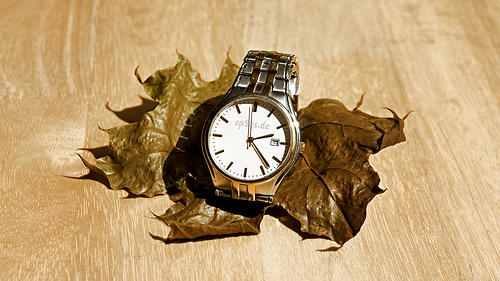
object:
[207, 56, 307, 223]
watch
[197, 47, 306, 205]
watch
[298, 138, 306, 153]
winder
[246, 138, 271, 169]
hands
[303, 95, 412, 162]
leaf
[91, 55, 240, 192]
leaf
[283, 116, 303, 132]
glare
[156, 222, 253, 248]
shadow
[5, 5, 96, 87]
platform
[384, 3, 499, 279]
platform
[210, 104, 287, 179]
2:24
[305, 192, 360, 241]
leaf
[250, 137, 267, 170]
hands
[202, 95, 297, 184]
clock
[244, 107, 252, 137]
arm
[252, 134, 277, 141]
arm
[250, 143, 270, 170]
arm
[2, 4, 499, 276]
class assignment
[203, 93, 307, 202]
watch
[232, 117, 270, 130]
website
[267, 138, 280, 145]
calendar window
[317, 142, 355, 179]
leaf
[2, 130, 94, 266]
surface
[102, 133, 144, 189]
leaf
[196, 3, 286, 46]
table